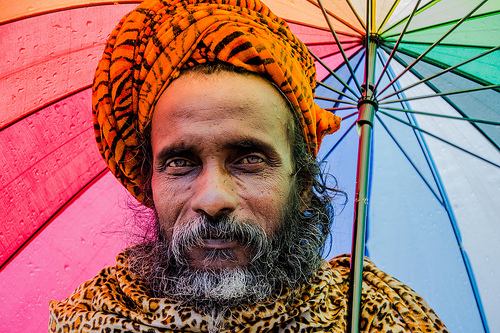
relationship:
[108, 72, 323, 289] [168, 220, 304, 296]
man has beard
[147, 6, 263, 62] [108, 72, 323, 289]
turban on man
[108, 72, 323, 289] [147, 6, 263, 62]
man with turban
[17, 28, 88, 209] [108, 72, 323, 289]
umbrella on man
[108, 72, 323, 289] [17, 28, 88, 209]
man with umbrella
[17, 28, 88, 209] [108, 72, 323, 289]
umbrella above man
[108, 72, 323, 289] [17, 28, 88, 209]
man holding umbrella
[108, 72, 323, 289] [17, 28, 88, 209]
man on umbrella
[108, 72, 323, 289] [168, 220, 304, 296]
man with beard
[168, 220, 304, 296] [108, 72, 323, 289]
beard on man